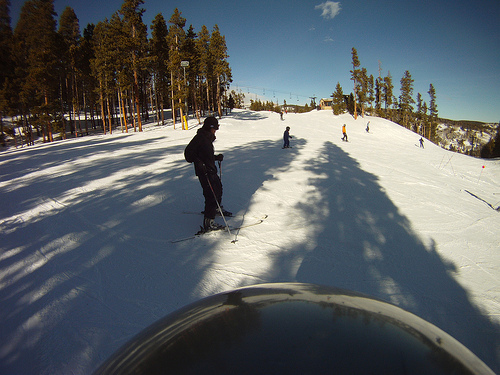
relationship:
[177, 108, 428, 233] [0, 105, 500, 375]
skiers skiing on hillside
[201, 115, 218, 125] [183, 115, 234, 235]
hat on top person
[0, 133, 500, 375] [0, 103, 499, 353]
shadow on snow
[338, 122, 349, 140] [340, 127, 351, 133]
person in orange coat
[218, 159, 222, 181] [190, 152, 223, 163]
ski poles in hands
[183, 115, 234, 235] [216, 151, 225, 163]
person wearing glove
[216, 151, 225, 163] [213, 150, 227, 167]
glove in hand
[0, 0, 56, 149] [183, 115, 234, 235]
tree behind person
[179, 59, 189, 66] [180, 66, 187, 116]
light on pole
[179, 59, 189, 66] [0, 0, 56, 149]
light among tree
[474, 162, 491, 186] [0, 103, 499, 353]
red flag standing gin snow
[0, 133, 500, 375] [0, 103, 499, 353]
shadow in snow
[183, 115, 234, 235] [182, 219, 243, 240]
person standing on ski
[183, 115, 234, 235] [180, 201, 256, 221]
person standing on ski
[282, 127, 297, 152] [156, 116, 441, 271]
kid in snow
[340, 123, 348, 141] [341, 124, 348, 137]
person wearing sweater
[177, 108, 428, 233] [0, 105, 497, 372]
skiers skiing down slope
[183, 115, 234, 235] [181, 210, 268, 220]
person on skis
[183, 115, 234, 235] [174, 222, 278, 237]
person on skis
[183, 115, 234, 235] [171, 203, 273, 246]
person on skis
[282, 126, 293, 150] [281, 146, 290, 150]
kid on skis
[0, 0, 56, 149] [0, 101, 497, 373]
tree on hillside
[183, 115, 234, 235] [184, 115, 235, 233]
person wearing clothing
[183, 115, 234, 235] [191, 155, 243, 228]
person holding ski poles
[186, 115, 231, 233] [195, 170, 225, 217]
person wearing pants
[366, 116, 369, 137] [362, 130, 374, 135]
person on skis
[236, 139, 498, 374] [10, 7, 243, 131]
shadow of tree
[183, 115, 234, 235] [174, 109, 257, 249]
person in clothing